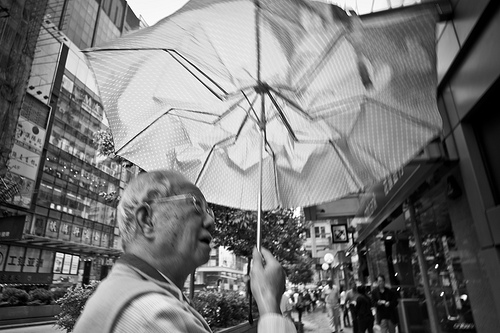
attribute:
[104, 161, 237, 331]
man — old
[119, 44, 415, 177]
umbrella — broken, open, black, white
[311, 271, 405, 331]
people — walking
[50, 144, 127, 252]
windows — shiny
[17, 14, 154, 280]
building — tall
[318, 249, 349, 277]
lights — circular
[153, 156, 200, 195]
head — balding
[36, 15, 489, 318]
photo — black, white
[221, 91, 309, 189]
support — metal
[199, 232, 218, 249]
mouth — open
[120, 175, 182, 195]
hair — grey